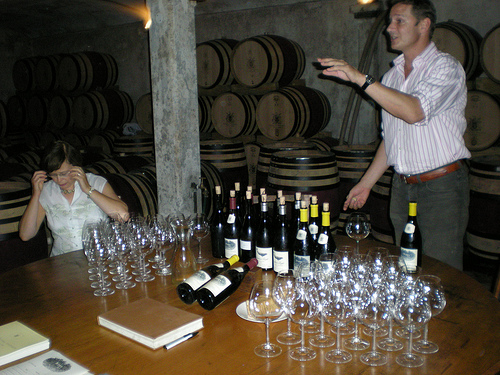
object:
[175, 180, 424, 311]
wine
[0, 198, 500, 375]
table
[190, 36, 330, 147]
keg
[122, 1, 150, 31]
light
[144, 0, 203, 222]
pillar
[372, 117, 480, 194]
ground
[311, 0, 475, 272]
guy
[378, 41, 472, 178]
shirt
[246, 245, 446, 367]
wine glasses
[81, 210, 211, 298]
wine glasses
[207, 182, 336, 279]
wine bottle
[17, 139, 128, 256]
woman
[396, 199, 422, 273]
wine bottle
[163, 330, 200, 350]
pen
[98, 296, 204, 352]
book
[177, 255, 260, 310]
wine bottle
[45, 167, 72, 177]
glasses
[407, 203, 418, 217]
yellow seal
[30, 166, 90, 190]
hands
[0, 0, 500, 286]
barrels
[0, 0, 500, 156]
wall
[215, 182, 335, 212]
cork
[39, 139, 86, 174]
hair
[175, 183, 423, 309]
bottle